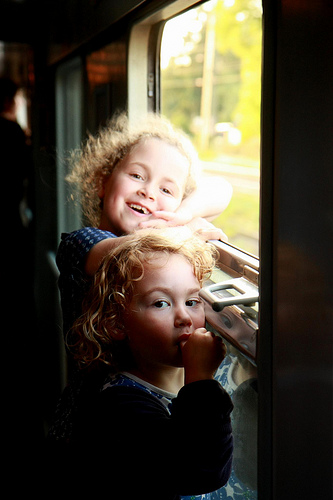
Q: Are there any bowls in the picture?
A: No, there are no bowls.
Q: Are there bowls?
A: No, there are no bowls.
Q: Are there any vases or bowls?
A: No, there are no bowls or vases.